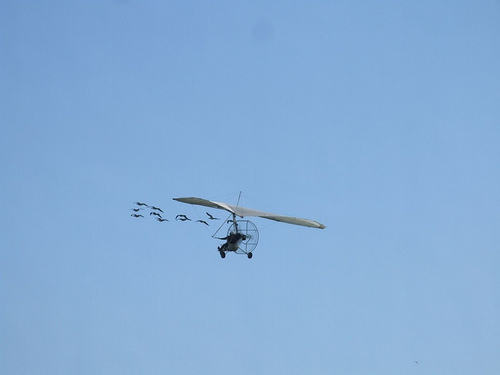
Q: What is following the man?
A: Birds.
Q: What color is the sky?
A: Blue.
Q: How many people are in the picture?
A: One.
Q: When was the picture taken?
A: Daytime.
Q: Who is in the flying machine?
A: A person.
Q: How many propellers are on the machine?
A: One.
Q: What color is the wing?
A: White.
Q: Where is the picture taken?
A: In mid-air.